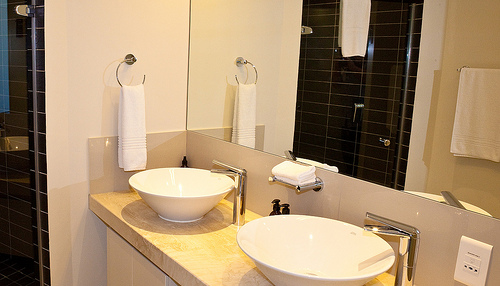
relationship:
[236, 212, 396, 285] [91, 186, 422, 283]
sink on countertop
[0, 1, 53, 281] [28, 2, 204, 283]
tiles on shower wall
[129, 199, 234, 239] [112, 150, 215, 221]
shadow on sink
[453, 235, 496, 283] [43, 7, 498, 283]
outlet on wall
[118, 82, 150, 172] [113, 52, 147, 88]
towel on rack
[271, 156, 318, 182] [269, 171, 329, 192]
towels on soap holder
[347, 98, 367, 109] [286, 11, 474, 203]
hinge on a door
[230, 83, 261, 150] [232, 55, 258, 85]
reflection of silver hook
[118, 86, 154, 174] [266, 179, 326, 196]
cloth on shelf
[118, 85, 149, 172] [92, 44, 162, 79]
towel on ring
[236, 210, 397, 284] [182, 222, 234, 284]
sink on counter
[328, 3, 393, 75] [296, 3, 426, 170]
towel on glass door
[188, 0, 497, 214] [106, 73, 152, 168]
mirror reflecting towel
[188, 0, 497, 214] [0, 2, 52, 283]
mirror reflecting shower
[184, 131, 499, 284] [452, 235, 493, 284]
backsplash with outlet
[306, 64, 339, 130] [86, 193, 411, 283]
tiles under counter